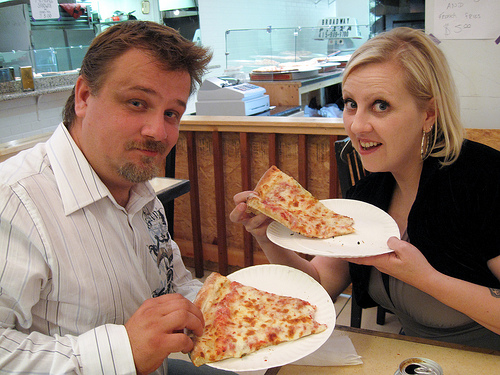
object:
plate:
[265, 196, 399, 261]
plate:
[183, 260, 336, 374]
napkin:
[296, 332, 363, 368]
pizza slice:
[246, 163, 352, 241]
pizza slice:
[185, 269, 327, 370]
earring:
[419, 128, 431, 156]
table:
[265, 324, 498, 374]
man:
[1, 16, 217, 373]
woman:
[226, 26, 496, 348]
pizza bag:
[57, 1, 88, 21]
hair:
[59, 19, 212, 125]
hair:
[340, 26, 467, 166]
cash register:
[195, 74, 269, 118]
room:
[3, 2, 496, 374]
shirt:
[0, 121, 205, 373]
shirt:
[332, 137, 499, 346]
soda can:
[395, 354, 441, 375]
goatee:
[116, 157, 160, 182]